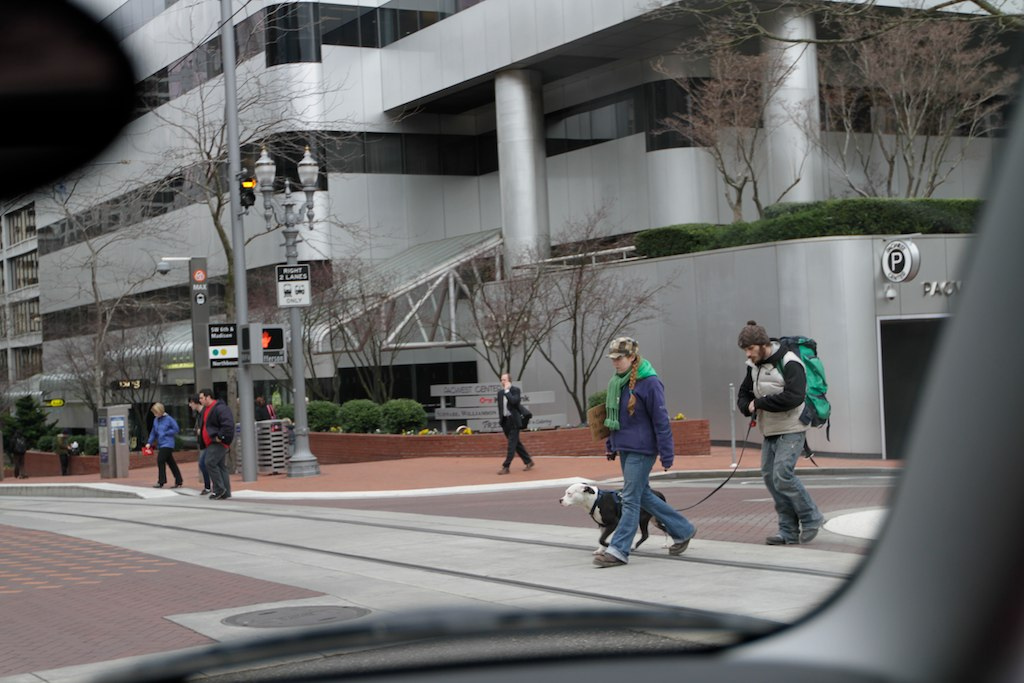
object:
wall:
[328, 172, 500, 287]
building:
[0, 0, 1024, 459]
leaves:
[413, 403, 422, 411]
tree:
[380, 398, 429, 433]